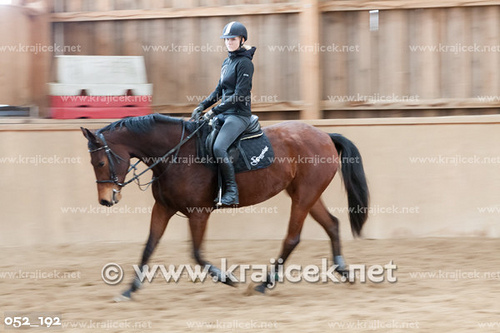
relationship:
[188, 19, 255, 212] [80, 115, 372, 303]
girl riding horse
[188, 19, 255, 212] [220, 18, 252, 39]
girl wearing helmet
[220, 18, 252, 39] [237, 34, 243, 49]
helmet has strip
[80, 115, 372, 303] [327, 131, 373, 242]
horse has tail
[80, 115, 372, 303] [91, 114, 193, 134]
horse has mane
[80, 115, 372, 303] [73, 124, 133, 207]
horse has head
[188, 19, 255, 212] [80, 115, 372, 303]
girl rides horse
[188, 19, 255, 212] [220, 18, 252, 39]
girl wears helmet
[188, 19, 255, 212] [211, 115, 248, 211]
girl has left leg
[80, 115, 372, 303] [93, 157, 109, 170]
horse has eye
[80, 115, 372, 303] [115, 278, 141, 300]
horse has hoof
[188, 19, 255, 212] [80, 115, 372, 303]
girl riding a horse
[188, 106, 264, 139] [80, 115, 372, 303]
saddle on horse